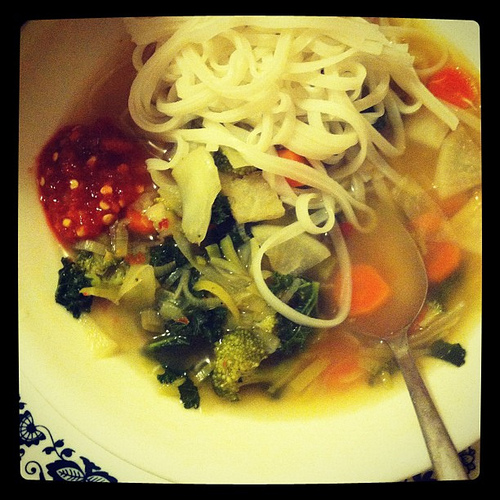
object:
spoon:
[325, 197, 470, 482]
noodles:
[118, 18, 461, 328]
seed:
[68, 176, 79, 189]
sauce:
[28, 115, 158, 247]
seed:
[100, 181, 114, 195]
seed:
[86, 152, 98, 166]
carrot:
[333, 263, 392, 316]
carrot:
[423, 240, 462, 283]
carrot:
[320, 339, 361, 388]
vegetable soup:
[55, 19, 481, 417]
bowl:
[20, 17, 484, 483]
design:
[21, 395, 120, 486]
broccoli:
[211, 328, 276, 404]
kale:
[54, 257, 93, 318]